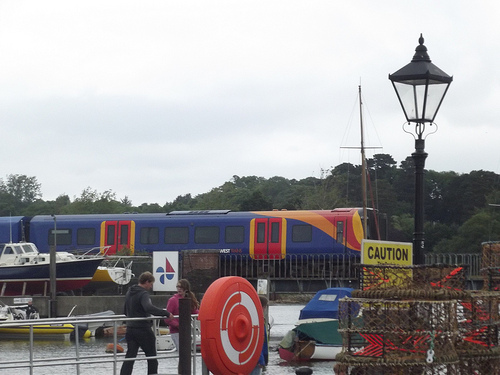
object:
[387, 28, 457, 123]
lamp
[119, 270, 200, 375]
people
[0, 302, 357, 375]
dock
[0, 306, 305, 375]
water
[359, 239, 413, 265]
sign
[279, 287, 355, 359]
boats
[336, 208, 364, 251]
trim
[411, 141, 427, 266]
post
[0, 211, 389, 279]
train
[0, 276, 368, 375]
tracks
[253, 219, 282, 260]
door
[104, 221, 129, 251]
door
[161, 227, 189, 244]
window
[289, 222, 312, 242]
window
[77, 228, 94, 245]
window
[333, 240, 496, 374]
containers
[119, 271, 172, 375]
man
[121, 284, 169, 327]
hoodie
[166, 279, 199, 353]
woman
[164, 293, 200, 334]
sweater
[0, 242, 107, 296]
boat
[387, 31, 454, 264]
street light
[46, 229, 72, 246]
window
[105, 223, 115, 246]
window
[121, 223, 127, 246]
window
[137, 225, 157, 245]
window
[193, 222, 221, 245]
window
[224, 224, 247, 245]
window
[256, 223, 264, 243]
window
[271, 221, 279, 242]
window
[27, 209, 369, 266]
train car